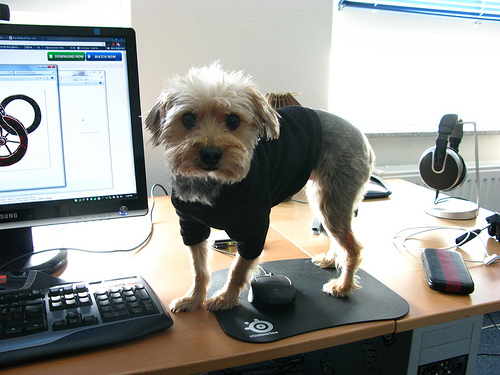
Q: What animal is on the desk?
A: Dog.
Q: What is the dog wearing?
A: Shirt.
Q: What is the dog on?
A: Mousepad.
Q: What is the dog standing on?
A: Desk.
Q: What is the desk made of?
A: Wood.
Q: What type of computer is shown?
A: Desktop.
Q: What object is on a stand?
A: Headphones.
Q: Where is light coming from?
A: Window.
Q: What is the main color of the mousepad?
A: Black.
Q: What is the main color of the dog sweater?
A: Brown.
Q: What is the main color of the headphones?
A: Black.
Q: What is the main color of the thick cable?
A: Black.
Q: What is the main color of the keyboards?
A: Black.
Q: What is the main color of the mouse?
A: Black.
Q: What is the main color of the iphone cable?
A: White.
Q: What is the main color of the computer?
A: Black.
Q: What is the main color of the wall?
A: White.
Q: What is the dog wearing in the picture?
A: Black shirt.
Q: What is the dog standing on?
A: Black mousepad.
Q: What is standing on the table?
A: Dog.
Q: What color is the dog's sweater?
A: Black.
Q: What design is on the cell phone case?
A: Stripe.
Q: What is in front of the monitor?
A: Keyboard.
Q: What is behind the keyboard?
A: Computer screen.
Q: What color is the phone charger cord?
A: White.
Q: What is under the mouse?
A: Mouse pad.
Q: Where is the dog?
A: On the desk.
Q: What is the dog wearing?
A: Sweater.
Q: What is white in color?
A: The wall.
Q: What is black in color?
A: Keyboard.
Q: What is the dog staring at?
A: The camera.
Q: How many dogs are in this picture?
A: One.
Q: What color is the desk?
A: Brown.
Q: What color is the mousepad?
A: Black.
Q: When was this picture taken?
A: Daytime.